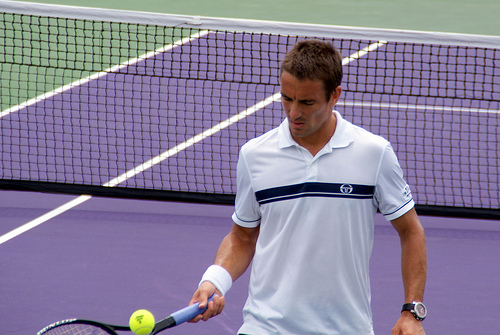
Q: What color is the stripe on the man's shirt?
A: Black.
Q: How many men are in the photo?
A: One.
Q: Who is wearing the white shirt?
A: The man.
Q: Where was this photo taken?
A: Tennis court.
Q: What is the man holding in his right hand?
A: Tennis racket.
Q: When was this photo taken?
A: Daytime.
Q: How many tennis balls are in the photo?
A: One.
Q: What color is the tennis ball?
A: Yellow.